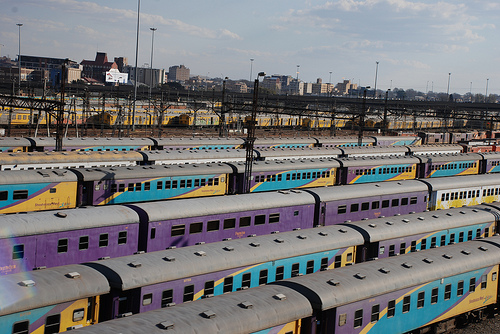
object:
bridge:
[0, 81, 500, 136]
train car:
[126, 188, 317, 252]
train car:
[336, 153, 421, 186]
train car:
[274, 239, 499, 334]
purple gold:
[378, 223, 500, 262]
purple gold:
[1, 181, 77, 213]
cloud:
[268, 0, 500, 87]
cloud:
[0, 0, 258, 77]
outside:
[0, 0, 498, 133]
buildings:
[0, 51, 500, 108]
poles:
[130, 0, 155, 138]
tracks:
[409, 305, 500, 334]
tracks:
[0, 117, 499, 134]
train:
[0, 199, 500, 334]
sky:
[0, 0, 500, 98]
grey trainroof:
[69, 282, 314, 334]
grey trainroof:
[266, 240, 500, 332]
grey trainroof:
[339, 207, 500, 244]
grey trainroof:
[130, 187, 316, 223]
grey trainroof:
[306, 180, 429, 203]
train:
[47, 234, 500, 334]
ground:
[405, 164, 453, 192]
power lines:
[0, 78, 499, 119]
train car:
[73, 161, 236, 205]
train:
[0, 134, 425, 153]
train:
[0, 162, 500, 270]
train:
[0, 152, 498, 213]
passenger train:
[0, 170, 500, 275]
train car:
[229, 153, 341, 192]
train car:
[415, 153, 484, 178]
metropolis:
[0, 0, 500, 152]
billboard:
[105, 72, 128, 84]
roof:
[0, 204, 140, 240]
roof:
[265, 241, 500, 313]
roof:
[126, 185, 315, 219]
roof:
[305, 179, 429, 202]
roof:
[0, 169, 79, 186]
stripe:
[189, 246, 357, 302]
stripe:
[333, 265, 499, 334]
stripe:
[98, 174, 228, 206]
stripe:
[244, 166, 336, 193]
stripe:
[425, 159, 479, 179]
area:
[0, 134, 500, 334]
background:
[0, 0, 499, 144]